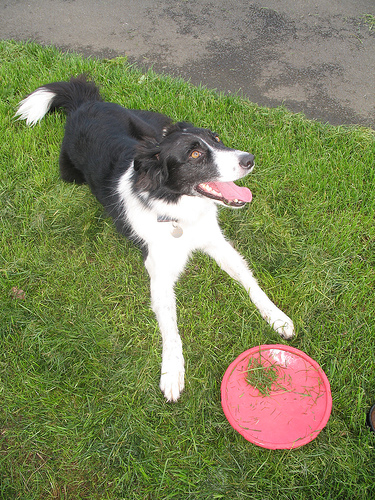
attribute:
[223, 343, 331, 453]
frisbee — plate, pink, possibly a lid, red, red toy, toy, round-edged, red dog toy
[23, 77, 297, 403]
dog — black, white, looking up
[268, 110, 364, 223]
yard grass — green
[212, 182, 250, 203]
tongue — pink, red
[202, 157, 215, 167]
eye — brown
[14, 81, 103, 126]
tail — black, white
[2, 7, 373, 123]
street — blacktop surface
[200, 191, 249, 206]
teeth — canine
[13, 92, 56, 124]
tip — white